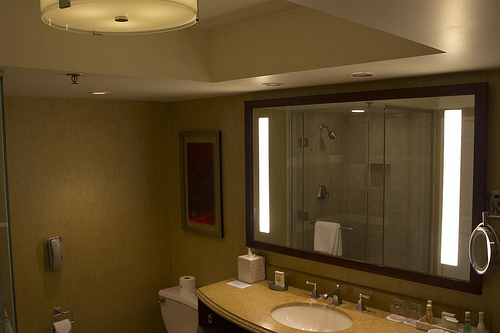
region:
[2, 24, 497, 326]
A bathroom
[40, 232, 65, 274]
A phone attached to the wall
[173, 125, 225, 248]
A painting above the toilet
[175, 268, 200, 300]
A roll of toilet paper on the back of the toilet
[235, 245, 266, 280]
A white box of tissues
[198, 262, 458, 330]
A light brown sink countertop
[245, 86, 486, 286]
A mirror on the wall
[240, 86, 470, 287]
A reflection of the shower in the mirror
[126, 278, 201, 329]
A white toilet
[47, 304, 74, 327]
A silver toilet paper holder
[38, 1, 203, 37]
The light is on.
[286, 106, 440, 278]
The shower can been seen in the mirror.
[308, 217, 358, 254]
A white bath towel can be seen in the mirror.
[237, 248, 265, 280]
A box of tissues.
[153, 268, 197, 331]
A toilet with a roll of toilet paper on top.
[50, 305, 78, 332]
A toilet paper roll dispenser.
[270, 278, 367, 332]
White bathroom sink with a silver faucet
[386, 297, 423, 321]
Empty glasses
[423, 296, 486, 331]
Lotions and soap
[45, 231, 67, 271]
A telephone is on the wall.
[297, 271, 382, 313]
Silver bathroom sink fixtures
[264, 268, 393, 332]
A bathroom sink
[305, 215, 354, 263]
A white towel hanging up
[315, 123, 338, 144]
A silver shower head nozzle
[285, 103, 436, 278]
Glass shower doors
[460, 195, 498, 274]
A round mirror attached to the wall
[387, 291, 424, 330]
Two glass cups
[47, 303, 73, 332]
A roll of toilet paper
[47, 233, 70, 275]
A landline beige phone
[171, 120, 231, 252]
A silver framed picture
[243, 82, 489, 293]
a framed mirror in a bathroom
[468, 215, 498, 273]
a small round mirror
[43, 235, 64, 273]
a landline phone on a wall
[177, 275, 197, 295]
a roll of toilet paper on top of a toilet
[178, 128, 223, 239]
a framed painting on a wall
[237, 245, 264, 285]
a box of tissue on a counter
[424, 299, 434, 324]
a yellow bottle of perfume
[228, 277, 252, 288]
a white rd on a counter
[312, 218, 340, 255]
a folded white towel on a rack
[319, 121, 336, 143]
a silver shower head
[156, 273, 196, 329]
roll of white toilet paper on toilet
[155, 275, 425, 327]
toilet next to long sink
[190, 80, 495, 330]
mirror hanging above sink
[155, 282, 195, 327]
silver handle on toilet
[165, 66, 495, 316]
framed mirror hanging on wall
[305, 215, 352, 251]
white towel hanging on silver railing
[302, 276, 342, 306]
silver knob next to faucet